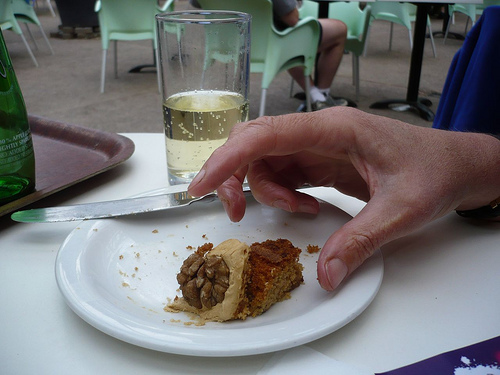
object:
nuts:
[204, 264, 217, 280]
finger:
[184, 109, 323, 204]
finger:
[216, 119, 250, 223]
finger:
[244, 161, 302, 216]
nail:
[322, 254, 350, 290]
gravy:
[164, 238, 252, 326]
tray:
[0, 114, 137, 230]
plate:
[51, 182, 384, 359]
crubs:
[118, 253, 127, 261]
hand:
[184, 103, 499, 293]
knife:
[9, 180, 315, 224]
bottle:
[0, 25, 37, 209]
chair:
[197, 0, 326, 123]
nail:
[220, 198, 233, 223]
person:
[183, 7, 499, 293]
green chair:
[92, 0, 177, 97]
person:
[189, 0, 358, 116]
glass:
[151, 9, 252, 188]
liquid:
[159, 90, 250, 183]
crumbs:
[302, 240, 322, 255]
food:
[160, 234, 306, 330]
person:
[184, 104, 499, 293]